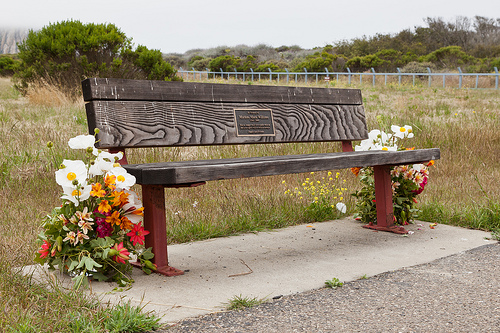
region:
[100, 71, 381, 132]
Back of bench is made of wood.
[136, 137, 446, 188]
Seat on bench is made of wood.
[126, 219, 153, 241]
Pink flower near bench.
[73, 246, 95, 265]
White flower near bench.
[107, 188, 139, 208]
Yellow flower near bench.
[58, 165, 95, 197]
White and yellow flower near bench.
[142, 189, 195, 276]
Leg of bench is reddish brown.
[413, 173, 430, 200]
Pink flower near bench.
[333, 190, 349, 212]
White flower near bench.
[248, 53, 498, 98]
Tall fence in grassy area.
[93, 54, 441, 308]
a wood bench with metal legs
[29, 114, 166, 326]
bouquet of flowers next to a bench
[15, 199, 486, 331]
a concrete slab with a bench connected to it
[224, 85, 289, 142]
a metal plaque on a bench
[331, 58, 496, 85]
a grey metal fence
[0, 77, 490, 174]
tall grass in a field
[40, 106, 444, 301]
two bouquet of flowers next to a bench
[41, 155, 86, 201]
a white flower with a yellow center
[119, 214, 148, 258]
a red flower in a bouquet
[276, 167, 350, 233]
a patch of yellow wild flowers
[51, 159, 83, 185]
A white and yellow flower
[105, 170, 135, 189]
A white and yellow flower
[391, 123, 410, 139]
A white and yellow flower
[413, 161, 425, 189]
A white and yellow flower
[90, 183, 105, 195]
A beautiful yellow flower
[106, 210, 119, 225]
A beautiful yellow flower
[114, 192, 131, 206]
A beautiful yellow flower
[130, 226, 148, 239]
A beautiful pink flower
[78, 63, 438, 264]
A wooden old seat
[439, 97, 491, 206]
Dry brown grass in the field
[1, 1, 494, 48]
cloud cover in sky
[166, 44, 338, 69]
line of trees on horizon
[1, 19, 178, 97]
green leaves on bush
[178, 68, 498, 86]
fence with bent poles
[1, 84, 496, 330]
tall dried grass surface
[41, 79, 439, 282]
flowers on each side of bench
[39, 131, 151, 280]
bouquet of colorful flowers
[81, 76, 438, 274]
bench made of weathered wood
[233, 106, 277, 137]
plaque on back of bench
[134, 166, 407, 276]
red metal legs of bench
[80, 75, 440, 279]
A brown wooden bench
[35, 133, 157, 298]
A bouquet of flowers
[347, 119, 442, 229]
A bouquet of flowers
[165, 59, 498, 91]
A grey fence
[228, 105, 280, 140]
A memorial plaque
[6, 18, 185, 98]
A loan evergreen bush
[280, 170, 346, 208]
Wild yellow flowers behind the bench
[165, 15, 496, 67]
Treeline in the background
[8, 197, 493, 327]
A cement platform for the bench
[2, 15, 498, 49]
A very overcast sky